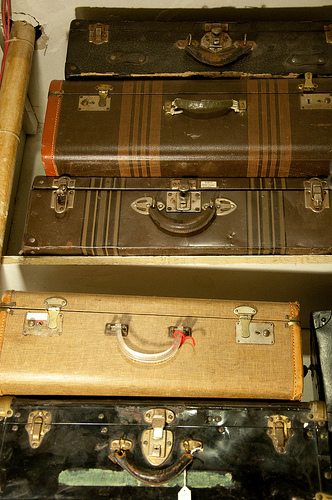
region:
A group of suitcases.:
[0, 19, 330, 496]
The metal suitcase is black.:
[0, 398, 330, 495]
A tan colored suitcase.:
[0, 279, 306, 395]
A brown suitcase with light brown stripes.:
[21, 169, 329, 252]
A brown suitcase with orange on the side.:
[21, 64, 329, 173]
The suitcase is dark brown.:
[57, 11, 329, 72]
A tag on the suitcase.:
[166, 459, 204, 496]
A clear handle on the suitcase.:
[102, 313, 200, 364]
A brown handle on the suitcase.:
[136, 182, 234, 236]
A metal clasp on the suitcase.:
[137, 407, 177, 467]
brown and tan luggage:
[46, 406, 180, 464]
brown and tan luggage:
[203, 425, 293, 461]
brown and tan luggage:
[65, 318, 207, 391]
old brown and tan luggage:
[50, 190, 163, 242]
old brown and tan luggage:
[195, 191, 289, 239]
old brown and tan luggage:
[75, 91, 184, 158]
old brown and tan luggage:
[263, 91, 331, 142]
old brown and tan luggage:
[101, 18, 195, 59]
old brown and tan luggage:
[223, 20, 304, 61]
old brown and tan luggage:
[103, 310, 211, 363]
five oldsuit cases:
[3, 2, 316, 498]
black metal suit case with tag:
[0, 392, 324, 490]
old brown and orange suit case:
[28, 67, 329, 173]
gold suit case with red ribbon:
[4, 276, 306, 404]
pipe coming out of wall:
[0, 7, 40, 260]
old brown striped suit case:
[6, 169, 328, 256]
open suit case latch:
[32, 171, 78, 219]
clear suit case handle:
[97, 313, 220, 362]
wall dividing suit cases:
[5, 232, 329, 307]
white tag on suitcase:
[147, 459, 234, 498]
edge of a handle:
[142, 463, 159, 478]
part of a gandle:
[149, 459, 171, 492]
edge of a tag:
[183, 483, 190, 492]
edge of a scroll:
[230, 377, 263, 404]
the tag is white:
[183, 487, 186, 498]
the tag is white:
[177, 491, 184, 499]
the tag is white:
[179, 488, 181, 499]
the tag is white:
[180, 489, 184, 498]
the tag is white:
[178, 488, 179, 490]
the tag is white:
[181, 491, 185, 499]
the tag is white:
[184, 491, 186, 496]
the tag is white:
[183, 489, 184, 490]